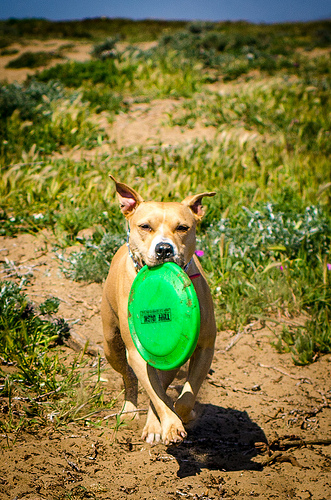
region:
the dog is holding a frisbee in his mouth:
[85, 188, 241, 398]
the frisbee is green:
[115, 260, 206, 373]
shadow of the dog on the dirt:
[150, 385, 283, 490]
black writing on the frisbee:
[131, 301, 177, 328]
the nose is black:
[142, 236, 176, 261]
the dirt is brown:
[51, 428, 165, 494]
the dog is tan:
[76, 193, 231, 452]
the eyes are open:
[130, 214, 194, 236]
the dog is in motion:
[80, 173, 253, 452]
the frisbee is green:
[139, 297, 179, 366]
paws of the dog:
[142, 419, 185, 447]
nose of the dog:
[158, 240, 170, 251]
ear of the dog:
[112, 181, 142, 213]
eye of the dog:
[138, 217, 154, 232]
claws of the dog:
[178, 430, 187, 439]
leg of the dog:
[135, 377, 177, 418]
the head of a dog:
[112, 179, 211, 269]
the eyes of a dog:
[140, 215, 193, 243]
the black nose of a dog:
[151, 241, 176, 257]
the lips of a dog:
[139, 249, 166, 272]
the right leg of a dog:
[117, 349, 180, 441]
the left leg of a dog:
[174, 347, 216, 437]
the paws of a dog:
[135, 412, 194, 453]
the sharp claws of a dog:
[143, 431, 185, 455]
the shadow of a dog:
[177, 368, 269, 480]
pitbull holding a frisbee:
[80, 171, 240, 443]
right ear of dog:
[102, 169, 136, 208]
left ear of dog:
[172, 182, 206, 217]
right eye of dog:
[131, 215, 151, 226]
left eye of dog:
[165, 219, 190, 233]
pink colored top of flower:
[188, 246, 205, 256]